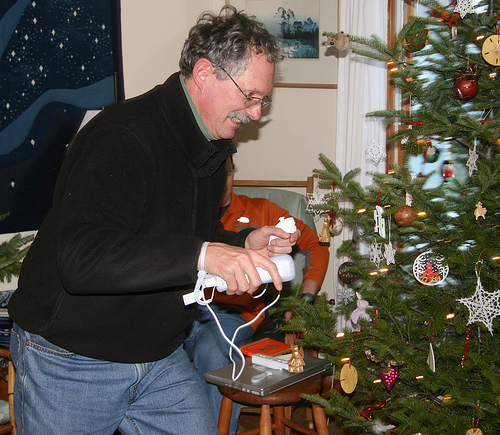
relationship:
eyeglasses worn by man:
[217, 65, 277, 114] [19, 5, 274, 433]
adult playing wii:
[2, 2, 299, 429] [192, 215, 299, 380]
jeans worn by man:
[9, 321, 217, 432] [170, 0, 295, 145]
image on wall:
[224, 0, 319, 59] [118, 0, 340, 316]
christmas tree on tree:
[270, 0, 499, 435] [353, 75, 483, 325]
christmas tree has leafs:
[270, 0, 499, 435] [415, 287, 441, 307]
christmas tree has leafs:
[270, 0, 499, 435] [361, 337, 383, 353]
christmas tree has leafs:
[270, 0, 499, 435] [466, 352, 488, 369]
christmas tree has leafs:
[270, 0, 499, 435] [472, 236, 488, 262]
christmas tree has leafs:
[270, 0, 499, 435] [393, 396, 422, 412]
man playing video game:
[7, 5, 301, 431] [189, 214, 300, 382]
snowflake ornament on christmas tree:
[453, 271, 497, 333] [268, 0, 498, 434]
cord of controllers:
[189, 300, 301, 396] [190, 212, 321, 300]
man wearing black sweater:
[7, 5, 301, 431] [2, 69, 256, 364]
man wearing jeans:
[7, 5, 301, 431] [6, 309, 243, 434]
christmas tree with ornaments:
[270, 0, 499, 435] [312, 199, 498, 331]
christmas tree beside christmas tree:
[270, 0, 499, 435] [270, 0, 499, 435]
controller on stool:
[250, 348, 294, 377] [215, 382, 330, 429]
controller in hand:
[265, 212, 300, 253] [238, 222, 300, 254]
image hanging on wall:
[224, 0, 319, 59] [120, 1, 337, 181]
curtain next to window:
[333, 49, 398, 335] [369, 7, 497, 317]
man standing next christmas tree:
[7, 5, 301, 431] [270, 0, 499, 435]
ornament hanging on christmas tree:
[395, 246, 465, 295] [270, 0, 499, 435]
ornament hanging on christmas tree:
[450, 263, 498, 342] [270, 0, 499, 435]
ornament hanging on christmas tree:
[325, 346, 371, 406] [270, 0, 499, 435]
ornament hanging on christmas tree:
[447, 67, 480, 107] [270, 0, 499, 435]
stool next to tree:
[245, 390, 320, 420] [343, 12, 497, 432]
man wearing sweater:
[7, 5, 301, 431] [6, 70, 257, 363]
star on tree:
[457, 276, 498, 338] [273, 1, 498, 432]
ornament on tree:
[374, 359, 417, 391] [223, 15, 485, 433]